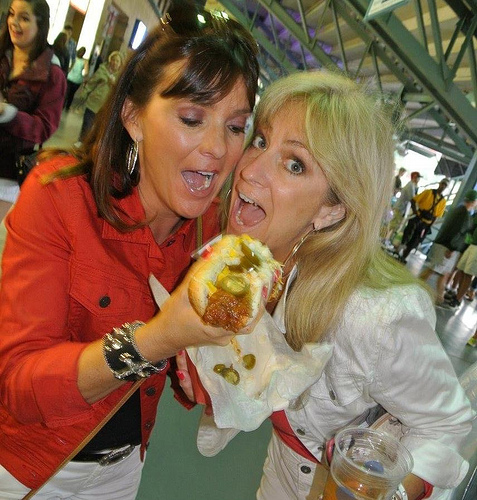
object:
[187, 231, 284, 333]
dog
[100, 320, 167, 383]
bracelet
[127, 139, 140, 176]
earring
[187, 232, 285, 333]
food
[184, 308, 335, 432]
paper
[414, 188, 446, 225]
shirt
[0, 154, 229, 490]
jacket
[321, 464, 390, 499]
beer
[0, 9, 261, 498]
women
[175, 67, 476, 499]
woman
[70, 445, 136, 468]
buckle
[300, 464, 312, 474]
button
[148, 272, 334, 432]
wrapper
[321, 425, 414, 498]
cup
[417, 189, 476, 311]
man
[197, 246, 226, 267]
nail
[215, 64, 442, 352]
blonde hair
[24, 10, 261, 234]
hair